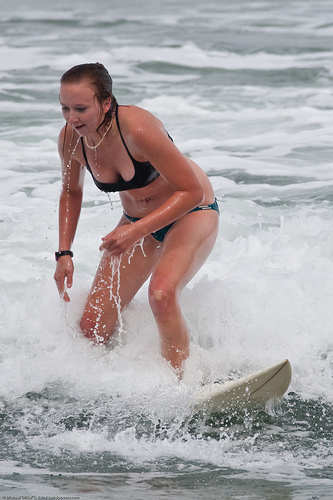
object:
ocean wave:
[14, 228, 166, 365]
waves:
[215, 157, 332, 180]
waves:
[260, 181, 332, 201]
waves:
[4, 45, 130, 65]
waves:
[0, 98, 57, 107]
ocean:
[3, 3, 331, 82]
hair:
[60, 60, 113, 111]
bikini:
[75, 105, 219, 245]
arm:
[56, 152, 84, 254]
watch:
[54, 249, 73, 260]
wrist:
[132, 219, 143, 244]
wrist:
[55, 248, 71, 259]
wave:
[114, 43, 331, 82]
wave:
[5, 274, 329, 392]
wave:
[4, 6, 261, 34]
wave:
[2, 124, 56, 198]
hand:
[99, 223, 138, 258]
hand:
[53, 247, 75, 305]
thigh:
[147, 208, 219, 294]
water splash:
[33, 363, 225, 459]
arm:
[134, 121, 206, 237]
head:
[58, 63, 113, 139]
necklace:
[85, 122, 112, 148]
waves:
[138, 19, 322, 121]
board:
[144, 356, 292, 427]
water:
[2, 1, 321, 498]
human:
[53, 61, 220, 383]